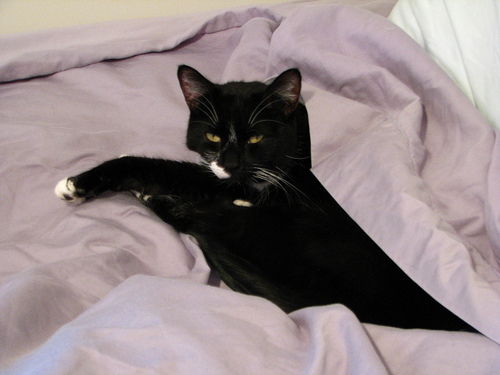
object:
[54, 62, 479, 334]
cat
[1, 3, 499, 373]
blanket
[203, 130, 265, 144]
eyes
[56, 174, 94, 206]
paw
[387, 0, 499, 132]
pillow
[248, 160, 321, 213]
whiskers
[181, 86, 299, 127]
whiskers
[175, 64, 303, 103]
ears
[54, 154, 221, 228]
legs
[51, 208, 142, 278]
wrinkles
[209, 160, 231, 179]
spot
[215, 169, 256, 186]
mouth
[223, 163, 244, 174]
nose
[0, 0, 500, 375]
fold